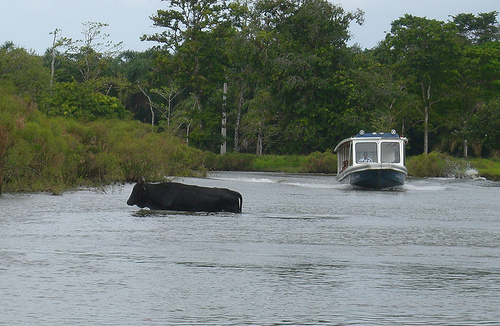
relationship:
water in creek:
[61, 217, 316, 307] [1, 162, 483, 320]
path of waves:
[233, 162, 467, 194] [214, 171, 456, 193]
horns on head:
[133, 173, 153, 184] [123, 175, 160, 206]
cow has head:
[123, 176, 245, 217] [123, 175, 160, 206]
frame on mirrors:
[349, 130, 407, 164] [337, 155, 357, 178]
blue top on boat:
[356, 132, 398, 137] [331, 129, 408, 189]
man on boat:
[358, 151, 373, 163] [326, 126, 417, 196]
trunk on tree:
[210, 64, 272, 157] [383, 0, 498, 170]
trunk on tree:
[420, 66, 447, 162] [278, 1, 379, 112]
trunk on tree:
[452, 133, 487, 170] [220, 2, 323, 147]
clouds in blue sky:
[9, 0, 50, 42] [0, 0, 500, 49]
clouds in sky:
[0, 0, 171, 56] [12, 0, 187, 67]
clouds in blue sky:
[359, 2, 379, 32] [2, 0, 179, 52]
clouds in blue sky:
[359, 2, 379, 32] [328, 0, 498, 49]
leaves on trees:
[2, 0, 499, 181] [4, 1, 498, 188]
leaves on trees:
[228, 50, 295, 100] [198, 33, 341, 118]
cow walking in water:
[127, 171, 280, 225] [1, 172, 499, 323]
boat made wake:
[331, 129, 408, 189] [231, 170, 452, 200]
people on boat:
[339, 158, 351, 168] [331, 129, 408, 189]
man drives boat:
[358, 151, 373, 163] [312, 121, 410, 190]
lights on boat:
[355, 121, 400, 138] [333, 125, 414, 195]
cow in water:
[127, 176, 243, 214] [1, 172, 499, 323]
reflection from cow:
[128, 209, 243, 218] [127, 176, 243, 214]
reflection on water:
[128, 209, 243, 218] [1, 172, 499, 323]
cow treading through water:
[127, 176, 243, 214] [118, 228, 385, 313]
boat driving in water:
[331, 129, 408, 189] [1, 172, 499, 323]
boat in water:
[123, 130, 406, 212] [1, 172, 499, 323]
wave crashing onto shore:
[439, 176, 499, 193] [212, 147, 499, 177]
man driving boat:
[356, 150, 372, 162] [329, 125, 412, 192]